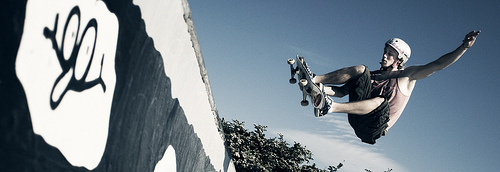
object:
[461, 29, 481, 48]
hand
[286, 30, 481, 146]
boy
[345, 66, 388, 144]
shorts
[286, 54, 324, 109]
skateboard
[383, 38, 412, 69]
helmet.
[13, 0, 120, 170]
painted face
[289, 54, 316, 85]
shoes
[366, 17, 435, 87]
ground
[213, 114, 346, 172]
tree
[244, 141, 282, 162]
leaves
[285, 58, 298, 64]
wheel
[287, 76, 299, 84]
wheel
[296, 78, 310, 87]
wheel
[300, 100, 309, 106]
wheel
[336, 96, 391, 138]
leg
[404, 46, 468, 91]
arm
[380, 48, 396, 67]
face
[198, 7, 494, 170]
sky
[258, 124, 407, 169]
cloud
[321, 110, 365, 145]
cloud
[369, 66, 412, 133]
tank top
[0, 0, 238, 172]
ramp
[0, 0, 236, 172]
wall